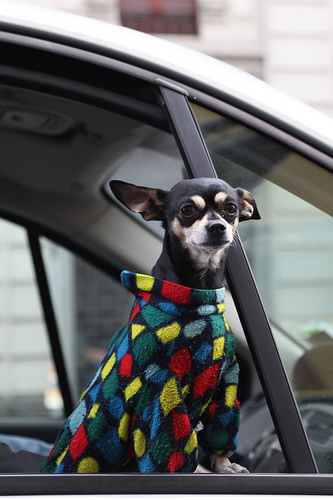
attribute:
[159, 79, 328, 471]
trim — black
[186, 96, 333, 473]
window — car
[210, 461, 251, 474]
paw — small, white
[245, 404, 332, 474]
panel — instrument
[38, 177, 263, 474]
dog — black, brown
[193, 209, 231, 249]
snout — black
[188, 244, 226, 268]
patch — white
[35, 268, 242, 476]
shirt — colorful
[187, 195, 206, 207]
eye brow — tan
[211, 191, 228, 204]
eye brow — tan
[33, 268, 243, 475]
jacket — multicolored , yellow, red, blue, green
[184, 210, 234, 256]
muzzle — dog's, tan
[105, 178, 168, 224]
ear — dog, black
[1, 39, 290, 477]
window — car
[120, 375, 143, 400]
square — yellow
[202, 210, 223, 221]
center — black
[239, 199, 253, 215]
inside — tan, pink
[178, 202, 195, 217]
eye — dog's, black